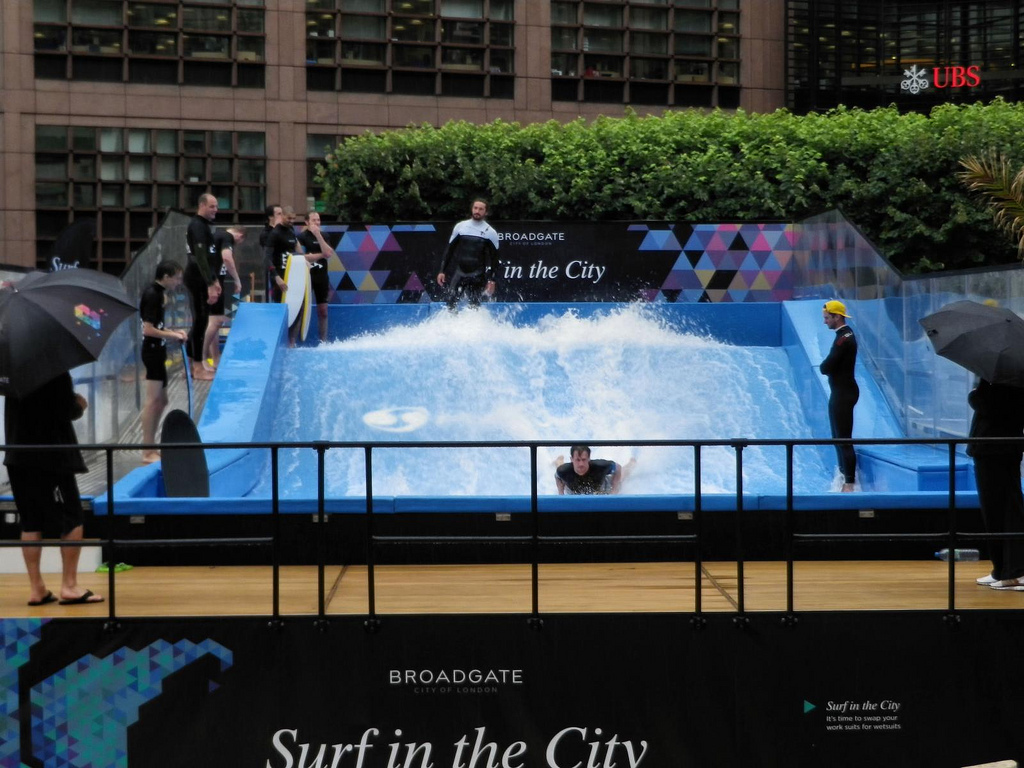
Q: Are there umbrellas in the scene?
A: Yes, there is an umbrella.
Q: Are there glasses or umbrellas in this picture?
A: Yes, there is an umbrella.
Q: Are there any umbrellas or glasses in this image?
A: Yes, there is an umbrella.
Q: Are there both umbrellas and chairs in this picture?
A: No, there is an umbrella but no chairs.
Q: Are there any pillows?
A: No, there are no pillows.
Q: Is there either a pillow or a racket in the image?
A: No, there are no pillows or rackets.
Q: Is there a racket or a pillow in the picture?
A: No, there are no pillows or rackets.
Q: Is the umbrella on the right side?
A: No, the umbrella is on the left of the image.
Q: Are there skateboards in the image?
A: Yes, there is a skateboard.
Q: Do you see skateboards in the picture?
A: Yes, there is a skateboard.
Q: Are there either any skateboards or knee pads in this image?
A: Yes, there is a skateboard.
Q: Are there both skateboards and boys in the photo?
A: No, there is a skateboard but no boys.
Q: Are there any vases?
A: No, there are no vases.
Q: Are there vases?
A: No, there are no vases.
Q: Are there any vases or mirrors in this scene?
A: No, there are no vases or mirrors.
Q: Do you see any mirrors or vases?
A: No, there are no vases or mirrors.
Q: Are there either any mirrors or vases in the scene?
A: No, there are no vases or mirrors.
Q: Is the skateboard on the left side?
A: Yes, the skateboard is on the left of the image.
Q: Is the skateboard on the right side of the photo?
A: No, the skateboard is on the left of the image.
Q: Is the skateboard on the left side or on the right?
A: The skateboard is on the left of the image.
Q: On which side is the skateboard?
A: The skateboard is on the left of the image.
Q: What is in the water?
A: The skateboard is in the water.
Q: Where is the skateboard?
A: The skateboard is in the water.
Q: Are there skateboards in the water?
A: Yes, there is a skateboard in the water.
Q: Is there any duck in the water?
A: No, there is a skateboard in the water.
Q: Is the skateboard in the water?
A: Yes, the skateboard is in the water.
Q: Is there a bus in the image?
A: No, there are no buses.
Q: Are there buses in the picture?
A: No, there are no buses.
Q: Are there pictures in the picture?
A: No, there are no pictures.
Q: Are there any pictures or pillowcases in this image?
A: No, there are no pictures or pillowcases.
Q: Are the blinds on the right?
A: No, the blinds are on the left of the image.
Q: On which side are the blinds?
A: The blinds are on the left of the image.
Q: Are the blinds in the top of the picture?
A: Yes, the blinds are in the top of the image.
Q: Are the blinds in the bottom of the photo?
A: No, the blinds are in the top of the image.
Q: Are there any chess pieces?
A: No, there are no chess pieces.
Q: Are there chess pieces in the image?
A: No, there are no chess pieces.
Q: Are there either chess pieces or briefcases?
A: No, there are no chess pieces or briefcases.